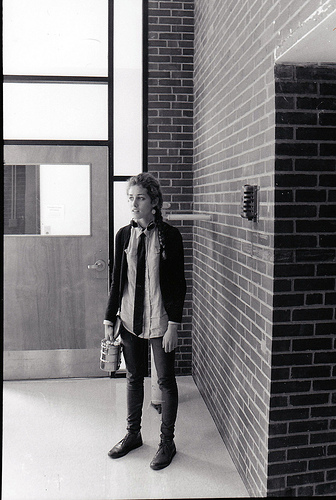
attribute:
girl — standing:
[96, 170, 197, 492]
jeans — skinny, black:
[122, 342, 168, 441]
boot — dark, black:
[152, 433, 186, 474]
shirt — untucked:
[124, 236, 167, 332]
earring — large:
[151, 208, 156, 216]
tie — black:
[135, 242, 145, 335]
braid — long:
[156, 216, 168, 257]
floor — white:
[4, 375, 192, 500]